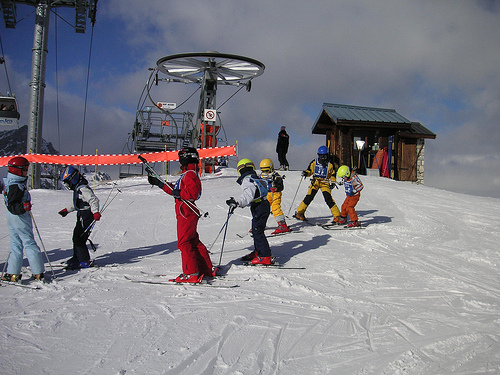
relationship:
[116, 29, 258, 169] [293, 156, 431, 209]
ski lift at top of hill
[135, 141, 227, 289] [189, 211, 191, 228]
skier in red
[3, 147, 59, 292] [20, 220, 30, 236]
child in blue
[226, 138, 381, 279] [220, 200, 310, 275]
kids preparing to ski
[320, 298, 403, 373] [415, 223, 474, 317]
ski tracks in snow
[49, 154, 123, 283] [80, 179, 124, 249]
kid sized ski poles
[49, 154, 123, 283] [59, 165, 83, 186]
kid with helmet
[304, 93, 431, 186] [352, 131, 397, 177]
shack with ski equipment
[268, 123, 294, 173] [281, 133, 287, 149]
person in all black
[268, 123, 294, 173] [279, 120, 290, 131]
person with helmet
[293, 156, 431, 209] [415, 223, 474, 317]
hill covered in snow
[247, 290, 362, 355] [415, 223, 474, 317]
ski marks in snow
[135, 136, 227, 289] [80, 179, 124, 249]
skier holding ski poles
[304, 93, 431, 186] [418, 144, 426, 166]
building made of stones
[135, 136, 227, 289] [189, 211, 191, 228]
skier helmet red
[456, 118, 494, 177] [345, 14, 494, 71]
puffy big clouds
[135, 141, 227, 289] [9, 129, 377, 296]
skier in group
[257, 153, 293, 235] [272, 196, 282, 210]
skier has a yellow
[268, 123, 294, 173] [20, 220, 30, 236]
person helmet blue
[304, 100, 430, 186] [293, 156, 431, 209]
shack atop hill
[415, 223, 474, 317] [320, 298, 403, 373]
snow with ski tracks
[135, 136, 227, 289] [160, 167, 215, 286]
skier with red snowsuit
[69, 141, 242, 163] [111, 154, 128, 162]
banner caution orange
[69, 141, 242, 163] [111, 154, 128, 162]
banner with orange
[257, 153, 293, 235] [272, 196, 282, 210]
skier in yellow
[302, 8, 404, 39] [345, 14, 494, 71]
blue sky with clouds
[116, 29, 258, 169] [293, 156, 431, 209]
ski lift atop of hill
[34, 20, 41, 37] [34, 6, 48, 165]
metal cable pole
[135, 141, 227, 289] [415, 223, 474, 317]
skier standing on snow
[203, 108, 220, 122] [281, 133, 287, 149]
white sign and black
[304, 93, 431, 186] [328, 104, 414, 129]
wooden shack with a shingled roof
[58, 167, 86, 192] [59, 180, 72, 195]
head angled down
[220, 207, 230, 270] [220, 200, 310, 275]
long and thin ski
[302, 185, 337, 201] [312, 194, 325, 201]
knees turned inward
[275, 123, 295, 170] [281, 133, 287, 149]
person wearing all black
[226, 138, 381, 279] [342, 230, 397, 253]
children skiing in a line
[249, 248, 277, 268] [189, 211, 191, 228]
ski boots red red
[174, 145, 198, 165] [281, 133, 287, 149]
ski helmet a black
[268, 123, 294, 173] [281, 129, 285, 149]
person and supervising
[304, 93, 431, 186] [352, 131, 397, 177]
shed to hold ski equipment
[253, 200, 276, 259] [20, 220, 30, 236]
snow pants blue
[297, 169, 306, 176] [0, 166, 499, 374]
top of a hill